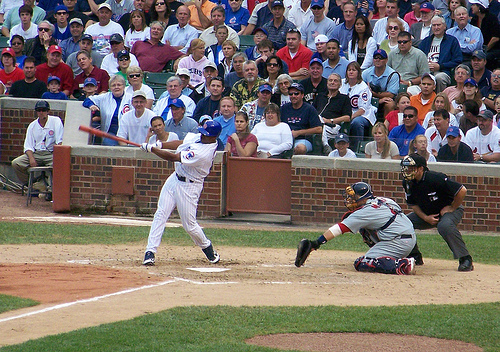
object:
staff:
[12, 98, 63, 187]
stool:
[26, 166, 53, 207]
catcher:
[294, 182, 417, 276]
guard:
[354, 256, 410, 275]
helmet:
[34, 100, 50, 112]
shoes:
[201, 243, 222, 263]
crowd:
[3, 2, 498, 178]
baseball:
[7, 72, 469, 352]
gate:
[223, 152, 287, 224]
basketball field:
[22, 179, 473, 324]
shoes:
[142, 250, 156, 265]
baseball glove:
[152, 140, 162, 149]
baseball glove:
[139, 142, 153, 153]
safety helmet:
[343, 182, 374, 211]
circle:
[244, 331, 481, 351]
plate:
[185, 267, 232, 274]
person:
[410, 73, 438, 119]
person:
[347, 15, 378, 65]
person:
[162, 6, 199, 52]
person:
[447, 6, 484, 53]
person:
[128, 20, 178, 73]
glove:
[295, 239, 320, 269]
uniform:
[144, 132, 218, 253]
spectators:
[12, 3, 498, 167]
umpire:
[400, 153, 473, 272]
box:
[76, 5, 498, 155]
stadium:
[1, 2, 499, 349]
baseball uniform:
[340, 194, 416, 263]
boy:
[327, 133, 356, 158]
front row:
[67, 111, 498, 163]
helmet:
[197, 120, 223, 137]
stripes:
[184, 188, 187, 211]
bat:
[78, 124, 140, 147]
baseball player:
[79, 121, 222, 266]